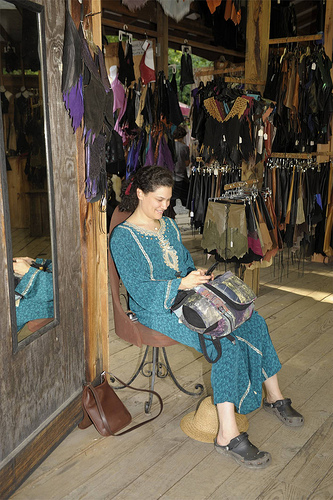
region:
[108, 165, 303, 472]
a woman in a blue dress sitting on a chair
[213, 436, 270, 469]
a woman's clog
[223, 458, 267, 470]
dirt on the bottom of a woman's clog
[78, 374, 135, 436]
a woman's handbag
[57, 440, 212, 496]
a wooden floor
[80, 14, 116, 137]
a leather vest hanging on a hanger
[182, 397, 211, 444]
a woman's straw hat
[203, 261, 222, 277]
a woman's phone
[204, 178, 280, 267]
leather skirts hanging on a rack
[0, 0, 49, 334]
a large mirror on a wall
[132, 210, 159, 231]
a woman's necklace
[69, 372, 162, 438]
a brown purse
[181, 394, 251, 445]
a hat sitting on the floor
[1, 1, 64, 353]
a long mirror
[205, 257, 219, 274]
a small black cellphone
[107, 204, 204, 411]
an old red chair with an iron bottom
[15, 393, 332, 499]
wooden floor planks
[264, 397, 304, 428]
black croc sandals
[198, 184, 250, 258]
a green and brown skirt on a hanger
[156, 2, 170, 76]
a wooden brown post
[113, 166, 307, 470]
woman in a blue dress sitting on a brown chair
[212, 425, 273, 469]
dirty black shoe on the woman's foot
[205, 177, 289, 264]
merchandise hanging from plastic hangers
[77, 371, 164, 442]
brown bag on the wooden floor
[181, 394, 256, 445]
tan straw hat behind the woman's foot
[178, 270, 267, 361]
bag on the woman's lap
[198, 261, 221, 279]
black cellphone in the woman's hands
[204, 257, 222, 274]
black flip phone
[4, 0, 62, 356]
long black framed mirror on the wall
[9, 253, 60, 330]
woman's dress reflecting in the mirror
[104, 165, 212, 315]
Middle aged woman smiling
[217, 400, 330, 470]
Black women's crockets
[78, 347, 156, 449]
Woman's brown purse on the ground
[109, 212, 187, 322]
Blue decorative dress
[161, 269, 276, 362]
Multi-color bag on a woman's lap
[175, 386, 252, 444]
Wicker sun hat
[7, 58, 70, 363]
Long mirror on the wooden wall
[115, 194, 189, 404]
Brown chair with a woman in it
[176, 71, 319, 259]
Several clothes in a clothes store.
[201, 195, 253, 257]
Green and brown woman's skirt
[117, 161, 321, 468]
lady sitting on chair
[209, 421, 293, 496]
lady wearing black croc shoes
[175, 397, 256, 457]
brown woven hat on floor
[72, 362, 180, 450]
brown handbag on floor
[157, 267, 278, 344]
colorful back pack on ladies lap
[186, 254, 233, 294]
lady holding cell phone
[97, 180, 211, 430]
lady sitting on brown chair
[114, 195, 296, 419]
lady wearing blue dress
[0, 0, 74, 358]
black framed mirror on wall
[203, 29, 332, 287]
clothes hanging on racks